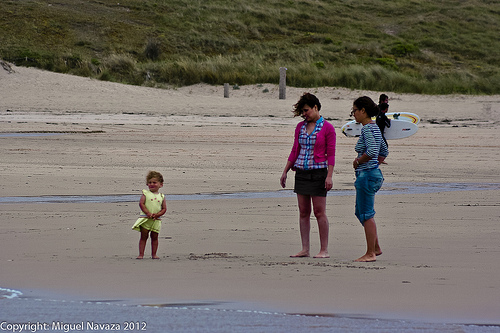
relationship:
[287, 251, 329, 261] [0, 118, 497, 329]
feet in sand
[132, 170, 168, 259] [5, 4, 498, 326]
child on beach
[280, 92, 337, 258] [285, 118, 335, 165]
lady wears shirt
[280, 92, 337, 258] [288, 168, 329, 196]
lady wears skirt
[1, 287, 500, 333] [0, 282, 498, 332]
ocean on shore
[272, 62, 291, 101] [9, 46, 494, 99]
pillar on distance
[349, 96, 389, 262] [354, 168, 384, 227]
girl wears capris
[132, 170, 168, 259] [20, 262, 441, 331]
child in beach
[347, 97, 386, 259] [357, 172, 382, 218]
girl wears jeans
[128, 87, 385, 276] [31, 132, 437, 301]
everyone on sand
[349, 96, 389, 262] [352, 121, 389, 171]
girl wears shirt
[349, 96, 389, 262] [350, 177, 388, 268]
girl has leg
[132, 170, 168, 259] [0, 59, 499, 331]
child on beach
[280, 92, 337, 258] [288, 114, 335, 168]
lady in pink sweater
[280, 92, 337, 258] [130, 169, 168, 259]
lady next to child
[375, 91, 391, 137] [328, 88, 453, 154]
people carrying surfboards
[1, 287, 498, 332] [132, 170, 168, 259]
ocean in front child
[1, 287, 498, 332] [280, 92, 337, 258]
ocean in front lady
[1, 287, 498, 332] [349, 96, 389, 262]
ocean in front girl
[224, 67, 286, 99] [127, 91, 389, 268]
poles behind people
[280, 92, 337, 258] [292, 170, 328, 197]
lady on skirt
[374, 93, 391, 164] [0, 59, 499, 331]
surfer walking beach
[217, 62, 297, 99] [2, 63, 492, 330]
poles in sand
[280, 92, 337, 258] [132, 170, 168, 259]
lady watching child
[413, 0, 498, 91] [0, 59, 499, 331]
green meadow near beach